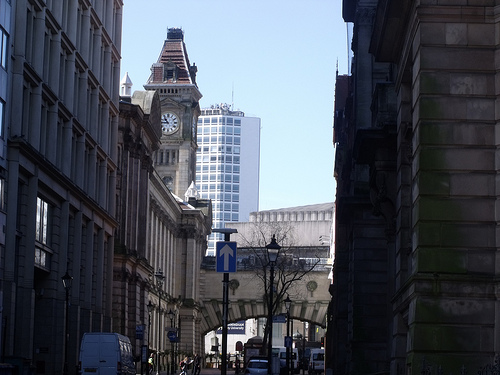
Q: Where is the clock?
A: On the tower.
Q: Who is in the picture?
A: No one.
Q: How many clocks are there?
A: One.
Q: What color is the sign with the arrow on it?
A: Blue.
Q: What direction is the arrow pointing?
A: Up.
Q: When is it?
A: Day time.